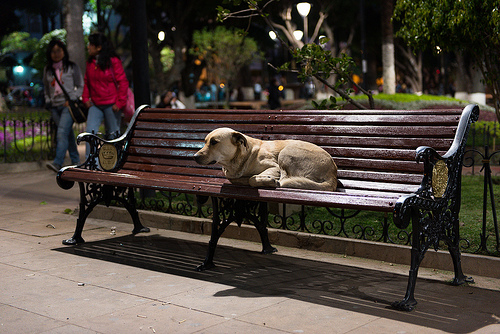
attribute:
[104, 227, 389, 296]
shadow — bench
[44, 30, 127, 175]
girls — together, walking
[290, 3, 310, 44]
street light — on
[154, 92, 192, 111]
people — sitting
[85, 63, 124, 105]
jacket — red, pink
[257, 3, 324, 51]
lights — safety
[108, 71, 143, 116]
bag — pink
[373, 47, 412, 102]
trunks — painted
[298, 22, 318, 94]
pole — illuminating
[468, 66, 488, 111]
trunk — painted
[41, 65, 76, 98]
jacket — gray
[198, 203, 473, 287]
legs — iron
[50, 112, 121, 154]
jeans — blue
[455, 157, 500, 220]
area — grassy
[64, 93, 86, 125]
bag — brown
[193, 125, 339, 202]
dog — staring, sitting, alone, resting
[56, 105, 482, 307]
bench — wooden, metal